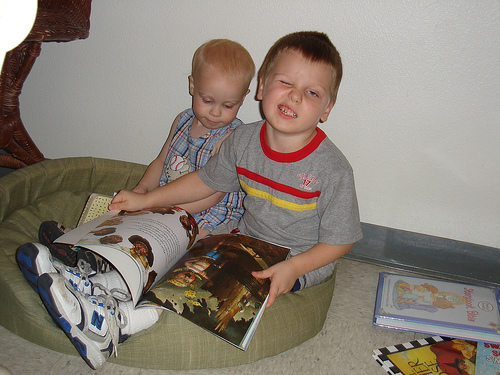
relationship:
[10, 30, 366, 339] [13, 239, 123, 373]
boy wearing sneakers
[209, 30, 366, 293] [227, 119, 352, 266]
boy wearing shirt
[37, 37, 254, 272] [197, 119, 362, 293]
boys in shirt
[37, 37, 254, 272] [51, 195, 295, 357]
boys reading a children's book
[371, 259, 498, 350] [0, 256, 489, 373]
children's book on floor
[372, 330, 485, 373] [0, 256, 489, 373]
children's book on floor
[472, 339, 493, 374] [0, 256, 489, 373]
children's book on floor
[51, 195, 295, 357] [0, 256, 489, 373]
children's book on floor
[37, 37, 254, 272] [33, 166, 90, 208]
boys sitting on a pouf